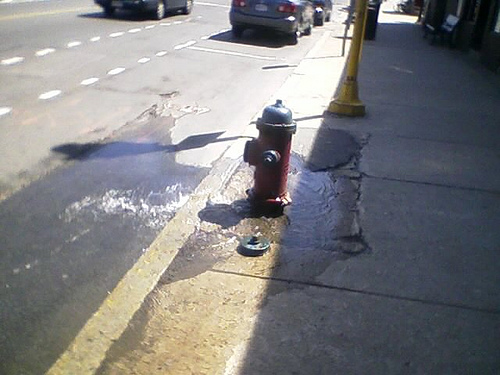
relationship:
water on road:
[0, 98, 217, 374] [1, 1, 349, 366]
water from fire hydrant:
[0, 98, 217, 374] [240, 100, 298, 216]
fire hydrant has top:
[240, 100, 298, 216] [256, 98, 297, 134]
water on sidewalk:
[156, 146, 337, 299] [43, 4, 495, 374]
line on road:
[128, 25, 145, 34] [1, 1, 349, 366]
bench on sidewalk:
[425, 13, 464, 49] [43, 4, 495, 374]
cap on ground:
[241, 235, 271, 254] [43, 4, 495, 374]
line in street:
[2, 14, 260, 119] [1, 1, 349, 366]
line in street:
[186, 46, 283, 62] [1, 1, 349, 366]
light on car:
[276, 4, 296, 14] [228, 0, 314, 46]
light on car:
[226, 0, 246, 8] [228, 0, 314, 46]